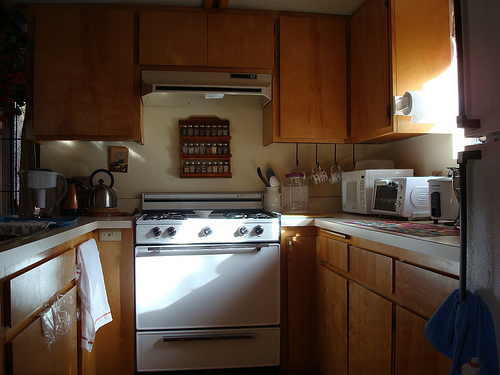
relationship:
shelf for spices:
[177, 116, 232, 179] [181, 125, 230, 175]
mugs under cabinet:
[291, 163, 356, 185] [262, 10, 351, 150]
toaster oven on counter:
[370, 175, 445, 221] [0, 210, 460, 272]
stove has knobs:
[134, 192, 281, 374] [150, 226, 264, 237]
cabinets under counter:
[0, 226, 462, 373] [0, 210, 460, 272]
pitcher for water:
[16, 167, 69, 218] [22, 206, 57, 218]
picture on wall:
[109, 146, 129, 174] [41, 106, 392, 199]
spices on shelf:
[181, 125, 230, 175] [177, 116, 232, 179]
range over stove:
[139, 70, 273, 111] [134, 192, 281, 374]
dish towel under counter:
[75, 238, 114, 353] [0, 210, 460, 272]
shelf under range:
[177, 116, 232, 179] [139, 70, 273, 111]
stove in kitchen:
[134, 192, 281, 374] [0, 1, 499, 374]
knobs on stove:
[150, 226, 264, 237] [134, 192, 281, 374]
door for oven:
[134, 242, 281, 329] [135, 244, 281, 331]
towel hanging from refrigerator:
[425, 287, 497, 374] [453, 0, 499, 375]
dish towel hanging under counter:
[75, 238, 114, 353] [0, 210, 460, 272]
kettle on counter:
[78, 169, 118, 209] [0, 210, 460, 272]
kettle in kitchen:
[78, 169, 118, 209] [0, 1, 499, 374]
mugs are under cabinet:
[291, 163, 356, 185] [262, 10, 351, 150]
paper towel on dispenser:
[404, 90, 439, 122] [393, 92, 410, 117]